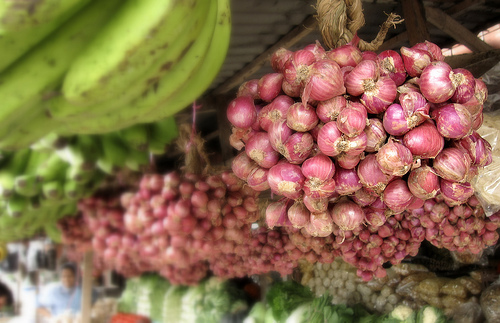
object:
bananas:
[170, 6, 212, 129]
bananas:
[71, 2, 161, 84]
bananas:
[17, 8, 103, 111]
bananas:
[2, 6, 49, 56]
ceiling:
[232, 0, 314, 45]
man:
[39, 264, 84, 316]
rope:
[312, 0, 399, 52]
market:
[0, 1, 493, 321]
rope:
[171, 117, 212, 172]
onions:
[72, 41, 500, 286]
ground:
[444, 147, 469, 195]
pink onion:
[304, 61, 346, 100]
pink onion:
[269, 162, 303, 200]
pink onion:
[433, 141, 468, 181]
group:
[20, 245, 40, 272]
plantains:
[3, 3, 230, 151]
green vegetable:
[419, 305, 446, 321]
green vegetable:
[384, 301, 414, 321]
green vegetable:
[283, 299, 340, 321]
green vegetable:
[242, 288, 295, 321]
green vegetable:
[202, 282, 227, 319]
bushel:
[337, 204, 425, 281]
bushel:
[420, 189, 498, 273]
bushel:
[192, 175, 292, 277]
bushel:
[124, 164, 240, 280]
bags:
[166, 288, 320, 318]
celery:
[112, 272, 445, 321]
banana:
[41, 7, 228, 126]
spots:
[84, 36, 183, 101]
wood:
[297, 248, 498, 316]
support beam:
[432, 10, 489, 53]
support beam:
[399, 0, 430, 42]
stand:
[5, 1, 462, 305]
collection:
[6, 7, 232, 117]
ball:
[227, 50, 484, 207]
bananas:
[0, 5, 233, 128]